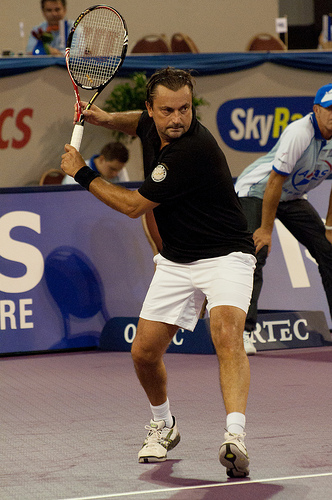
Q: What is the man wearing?
A: White shorts.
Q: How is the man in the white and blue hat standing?
A: He is bending foward.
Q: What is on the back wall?
A: Advertisement.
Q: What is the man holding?
A: A tennis racket.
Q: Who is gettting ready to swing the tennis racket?
A: The man.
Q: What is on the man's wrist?
A: A black wristband?.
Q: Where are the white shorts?
A: On the man playing tennis.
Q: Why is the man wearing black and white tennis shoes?
A: He is playing tennis.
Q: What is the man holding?
A: Tennis racket.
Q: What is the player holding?
A: A racket.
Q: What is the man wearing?
A: Tennis clothes.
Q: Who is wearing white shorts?
A: The man.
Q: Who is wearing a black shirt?
A: A man.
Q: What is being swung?
A: A tennis racket.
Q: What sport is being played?
A: Tennis.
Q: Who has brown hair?
A: The man.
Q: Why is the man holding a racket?
A: To hit the ball.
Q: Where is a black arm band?
A: On man's left arm.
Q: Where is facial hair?
A: On man's face.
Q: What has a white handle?
A: Tennis racket.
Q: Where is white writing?
A: On blue wall.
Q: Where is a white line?
A: On the court.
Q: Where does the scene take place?
A: At a tennis match.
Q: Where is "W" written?
A: On tennis racket.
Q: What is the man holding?
A: A racquet.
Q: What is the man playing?
A: Tennis.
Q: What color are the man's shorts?
A: White.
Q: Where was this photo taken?
A: At a tennis court.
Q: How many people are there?
A: Four.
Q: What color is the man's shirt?
A: Black.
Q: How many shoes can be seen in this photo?
A: Three.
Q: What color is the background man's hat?
A: Blue.